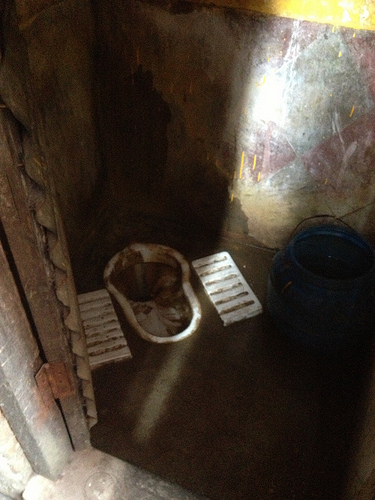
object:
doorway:
[0, 410, 202, 500]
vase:
[265, 212, 374, 357]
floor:
[191, 251, 264, 327]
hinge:
[35, 363, 75, 408]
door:
[0, 4, 98, 477]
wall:
[165, 11, 352, 247]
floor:
[72, 201, 374, 500]